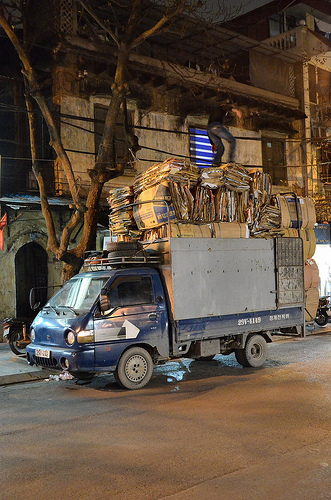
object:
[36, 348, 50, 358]
license plate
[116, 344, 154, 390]
rim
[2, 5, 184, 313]
tree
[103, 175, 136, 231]
boxes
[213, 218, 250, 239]
carton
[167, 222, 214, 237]
carton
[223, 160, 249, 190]
carton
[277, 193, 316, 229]
carton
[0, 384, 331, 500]
road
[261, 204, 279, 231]
carton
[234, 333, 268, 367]
wheel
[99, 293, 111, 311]
mirror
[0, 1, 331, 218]
building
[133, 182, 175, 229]
card board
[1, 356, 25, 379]
sidewalk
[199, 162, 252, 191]
boxes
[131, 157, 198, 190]
boxes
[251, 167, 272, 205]
boxes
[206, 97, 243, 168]
man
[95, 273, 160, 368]
door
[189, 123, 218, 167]
window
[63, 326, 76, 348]
headlights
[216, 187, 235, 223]
compacted boxes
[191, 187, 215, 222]
carton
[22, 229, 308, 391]
pick up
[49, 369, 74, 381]
litter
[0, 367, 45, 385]
curb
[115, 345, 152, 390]
wheel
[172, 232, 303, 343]
truck bed